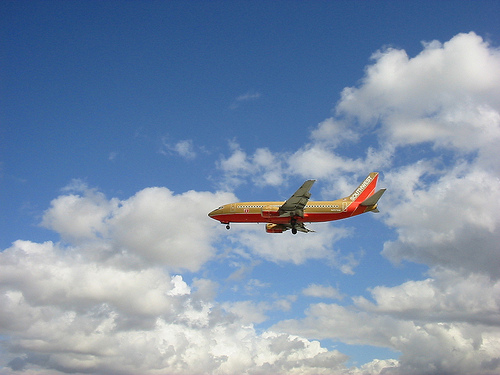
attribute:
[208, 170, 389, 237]
plane — gold, passenger jet, flying, beige, preparing to land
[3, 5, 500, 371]
sky — blue, cloudy, bright, blue in color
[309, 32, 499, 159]
cloud — fluffy, white, white in color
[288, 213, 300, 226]
wheel — down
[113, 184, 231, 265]
cloud — fluffy, puffy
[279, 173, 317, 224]
wing — silver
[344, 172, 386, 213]
tail fin — white